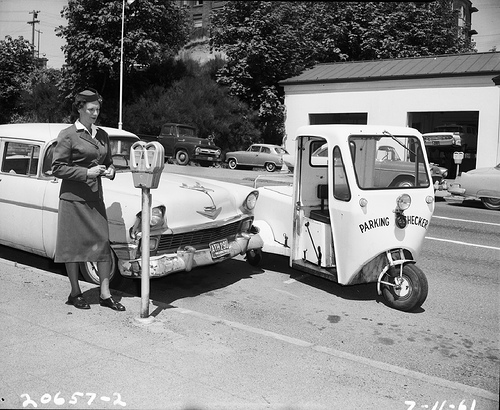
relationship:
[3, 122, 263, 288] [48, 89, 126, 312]
car checked by clerk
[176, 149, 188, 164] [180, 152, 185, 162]
white tire has hub cap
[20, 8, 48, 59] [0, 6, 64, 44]
pole supporting wires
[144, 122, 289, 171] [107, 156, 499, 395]
cars parked on street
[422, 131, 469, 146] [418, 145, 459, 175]
car on lift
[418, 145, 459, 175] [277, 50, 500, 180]
lift in building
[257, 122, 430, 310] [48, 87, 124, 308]
cart belongs to clerk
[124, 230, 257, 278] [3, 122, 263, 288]
bumper on car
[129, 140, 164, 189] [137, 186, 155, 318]
meter attached to pole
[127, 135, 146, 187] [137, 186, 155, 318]
meter attached to pole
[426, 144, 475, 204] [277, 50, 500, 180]
meter in front of building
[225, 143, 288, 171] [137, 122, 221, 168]
car parked in front of cars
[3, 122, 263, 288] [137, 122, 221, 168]
car parked in front of cars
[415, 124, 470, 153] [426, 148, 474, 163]
car raised on car lift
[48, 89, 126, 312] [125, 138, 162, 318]
clerk tending to meter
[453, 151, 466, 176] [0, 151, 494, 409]
meter on side of street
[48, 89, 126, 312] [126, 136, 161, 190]
clerk checking meter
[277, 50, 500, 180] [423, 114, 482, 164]
building servicing car